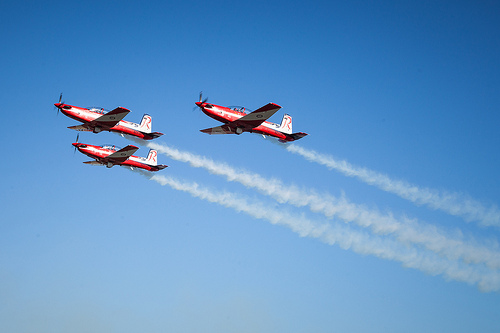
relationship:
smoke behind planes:
[176, 132, 489, 302] [46, 80, 308, 203]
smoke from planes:
[176, 132, 489, 302] [46, 80, 308, 203]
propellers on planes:
[46, 98, 213, 164] [46, 80, 308, 203]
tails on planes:
[138, 96, 305, 182] [46, 80, 308, 203]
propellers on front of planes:
[46, 98, 213, 164] [46, 80, 308, 203]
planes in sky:
[46, 80, 308, 203] [0, 3, 498, 331]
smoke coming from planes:
[176, 132, 489, 302] [46, 80, 308, 203]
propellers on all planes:
[46, 98, 213, 164] [46, 80, 308, 203]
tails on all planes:
[138, 96, 305, 182] [46, 80, 308, 203]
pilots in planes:
[82, 92, 251, 175] [46, 80, 308, 203]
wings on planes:
[103, 80, 284, 179] [46, 80, 308, 203]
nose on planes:
[39, 93, 220, 164] [46, 80, 308, 203]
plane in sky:
[192, 86, 306, 150] [0, 3, 498, 331]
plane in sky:
[47, 89, 176, 140] [0, 3, 498, 331]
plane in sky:
[60, 132, 175, 181] [0, 3, 498, 331]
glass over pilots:
[86, 90, 251, 176] [82, 92, 251, 175]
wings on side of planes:
[103, 80, 284, 179] [46, 80, 308, 203]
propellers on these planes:
[46, 98, 213, 164] [46, 80, 308, 203]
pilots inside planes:
[82, 92, 251, 175] [46, 80, 308, 203]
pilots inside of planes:
[82, 92, 251, 175] [46, 80, 308, 203]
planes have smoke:
[46, 80, 308, 203] [176, 132, 489, 302]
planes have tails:
[46, 80, 308, 203] [138, 96, 305, 182]